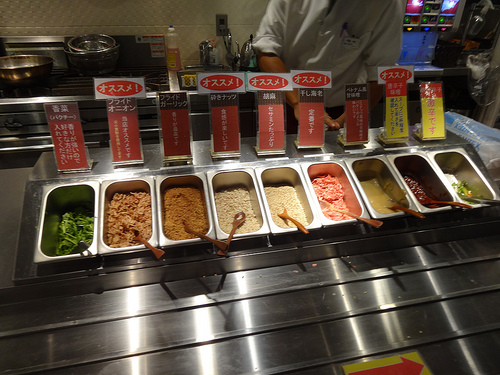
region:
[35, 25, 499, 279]
condaments on a display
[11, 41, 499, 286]
condaments in container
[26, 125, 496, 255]
spoons in silver container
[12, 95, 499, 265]
spoons in container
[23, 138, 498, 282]
wooden spoons in container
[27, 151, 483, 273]
wooden spoons in silver containers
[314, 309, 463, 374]
an arrow on the counter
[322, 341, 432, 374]
a red arrow on counter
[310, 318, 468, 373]
counter with red arrow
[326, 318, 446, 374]
counter with arrow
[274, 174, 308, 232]
rice is in thecontainer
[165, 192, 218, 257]
brwon rice is in the container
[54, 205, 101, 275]
vegetables are green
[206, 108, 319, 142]
the leeters are in chinese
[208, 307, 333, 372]
the surface is reflective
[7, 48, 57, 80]
the panis on the cooker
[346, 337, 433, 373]
the arrow is red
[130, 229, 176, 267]
the cooking stick is wooden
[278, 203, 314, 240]
the cooking stick is wooden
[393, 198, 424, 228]
the cooking stick is wooden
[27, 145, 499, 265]
containers on a buffet line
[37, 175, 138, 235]
container of green food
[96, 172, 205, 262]
two containers of brown food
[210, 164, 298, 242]
two containers of white food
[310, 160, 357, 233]
container of pink food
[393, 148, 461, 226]
container of red food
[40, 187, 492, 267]
nine handles sticking out of nine containers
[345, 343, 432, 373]
yellow sticker with red arrow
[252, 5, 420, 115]
man standing behind buffet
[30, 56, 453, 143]
labels behind the containers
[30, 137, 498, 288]
good on a buffet bar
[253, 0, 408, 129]
man in a light gray shirt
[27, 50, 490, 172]
signs in Chinese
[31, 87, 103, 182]
red sign on a buffet bar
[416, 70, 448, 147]
yellow and red sign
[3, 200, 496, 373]
metal buffet bar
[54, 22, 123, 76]
metal bowls on a stove top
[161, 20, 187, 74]
plastic bottle of oil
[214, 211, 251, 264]
wooden serving spoonn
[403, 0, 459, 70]
drink dispenser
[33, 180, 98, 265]
a metal container of food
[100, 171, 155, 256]
a metal container of food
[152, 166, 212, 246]
a metal container of food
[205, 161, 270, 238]
a metal container of food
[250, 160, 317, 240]
a metal container of food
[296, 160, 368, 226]
a metal container of food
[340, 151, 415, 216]
a metal container of food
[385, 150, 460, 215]
a metal container of food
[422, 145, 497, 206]
a metal container of food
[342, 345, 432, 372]
a yellow and red arrow sign